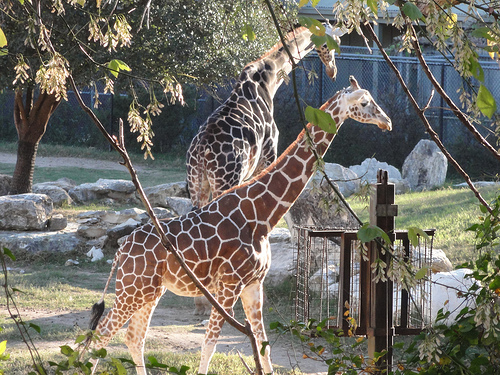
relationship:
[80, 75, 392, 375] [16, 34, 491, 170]
giraffe behind fences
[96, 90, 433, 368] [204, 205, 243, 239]
giraffe with spots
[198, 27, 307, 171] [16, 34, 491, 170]
giraffe walking towards fences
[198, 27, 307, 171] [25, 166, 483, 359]
giraffe on ground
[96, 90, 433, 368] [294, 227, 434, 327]
giraffe next to cage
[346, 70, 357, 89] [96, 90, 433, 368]
ear of giraffe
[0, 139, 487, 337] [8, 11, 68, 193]
rocks in front of tree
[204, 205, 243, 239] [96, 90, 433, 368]
spots on giraffe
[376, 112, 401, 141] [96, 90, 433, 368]
nose on giraffe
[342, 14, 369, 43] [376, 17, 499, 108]
leaves on branches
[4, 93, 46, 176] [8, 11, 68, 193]
trunk of tree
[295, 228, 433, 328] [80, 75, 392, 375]
feeder for giraffe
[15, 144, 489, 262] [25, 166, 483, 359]
rocks on ground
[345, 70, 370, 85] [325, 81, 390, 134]
horns on head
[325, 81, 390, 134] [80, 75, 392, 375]
head of giraffe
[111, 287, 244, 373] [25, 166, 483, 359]
path along ground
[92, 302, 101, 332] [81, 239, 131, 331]
hair on tail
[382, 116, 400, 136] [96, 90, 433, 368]
mouth of giraffe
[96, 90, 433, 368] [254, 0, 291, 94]
giraffe has neck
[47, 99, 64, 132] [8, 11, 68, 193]
branch of tree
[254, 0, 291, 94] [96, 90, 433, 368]
neck of giraffe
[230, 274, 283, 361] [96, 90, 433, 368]
leg of giraffe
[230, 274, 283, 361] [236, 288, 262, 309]
leg has patches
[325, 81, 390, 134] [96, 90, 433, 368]
head of giraffe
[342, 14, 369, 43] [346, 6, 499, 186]
leaves on tree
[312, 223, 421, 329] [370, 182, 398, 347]
wire attached to wood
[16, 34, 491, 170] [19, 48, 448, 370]
fences divides pasture